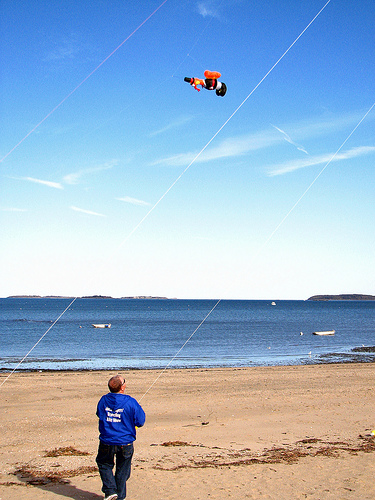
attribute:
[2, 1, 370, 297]
sky — bright, blue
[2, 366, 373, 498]
beach — tan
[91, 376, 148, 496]
man — still, standing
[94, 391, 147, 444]
shirt — bright, blue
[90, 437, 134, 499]
jeans — blue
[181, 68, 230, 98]
kite — large, colorful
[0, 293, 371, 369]
water — blue, dark, large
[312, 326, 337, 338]
boat — small, floating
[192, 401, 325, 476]
sand — tan